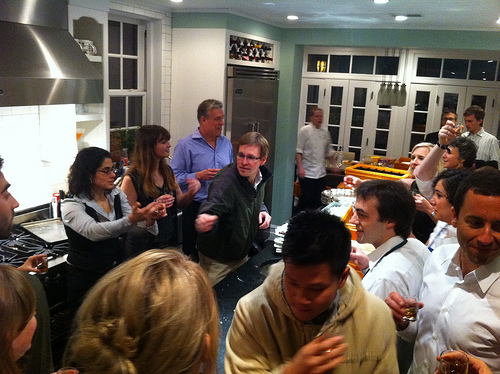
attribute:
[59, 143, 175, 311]
lady — wearing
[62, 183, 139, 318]
dress — black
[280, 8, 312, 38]
light — is hanging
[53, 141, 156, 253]
woman — is standing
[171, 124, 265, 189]
shirt — is blue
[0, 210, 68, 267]
stove top — is black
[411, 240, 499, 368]
shirt — is white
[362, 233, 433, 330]
shirt — is white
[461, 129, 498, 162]
shirt — is white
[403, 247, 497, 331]
shirt — is white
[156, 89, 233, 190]
shirt — is purple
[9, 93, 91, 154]
light — is shining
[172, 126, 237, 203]
shirt — is blue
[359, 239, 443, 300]
shirt — is white